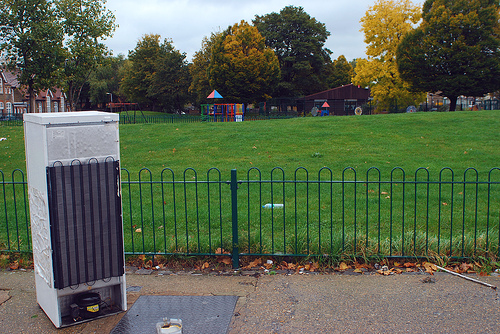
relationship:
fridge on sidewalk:
[23, 110, 127, 330] [1, 260, 499, 332]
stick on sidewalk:
[422, 260, 497, 289] [234, 266, 498, 332]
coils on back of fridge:
[28, 152, 135, 291] [23, 110, 127, 330]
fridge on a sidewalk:
[23, 110, 127, 330] [1, 260, 499, 332]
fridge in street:
[23, 110, 127, 330] [1, 264, 498, 331]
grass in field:
[0, 108, 499, 254] [1, 112, 498, 255]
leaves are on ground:
[144, 240, 474, 290] [10, 216, 498, 306]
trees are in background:
[1, 0, 499, 115] [2, 17, 497, 118]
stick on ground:
[410, 251, 498, 301] [265, 191, 489, 318]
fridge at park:
[9, 107, 144, 302] [110, 104, 497, 249]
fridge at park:
[23, 110, 127, 330] [140, 120, 480, 232]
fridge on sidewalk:
[23, 110, 127, 330] [224, 272, 497, 326]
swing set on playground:
[114, 96, 145, 121] [192, 78, 416, 122]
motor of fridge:
[63, 292, 100, 316] [23, 110, 127, 330]